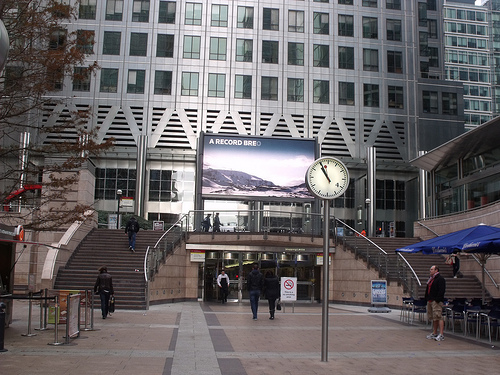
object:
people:
[93, 266, 116, 318]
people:
[246, 261, 266, 319]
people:
[216, 269, 230, 304]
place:
[0, 299, 500, 374]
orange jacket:
[360, 230, 367, 237]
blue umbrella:
[394, 225, 499, 256]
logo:
[372, 281, 386, 302]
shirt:
[424, 271, 447, 303]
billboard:
[192, 130, 322, 235]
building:
[0, 0, 500, 311]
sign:
[194, 131, 320, 203]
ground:
[0, 297, 497, 375]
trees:
[0, 0, 116, 348]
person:
[125, 216, 140, 252]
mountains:
[201, 162, 312, 199]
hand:
[319, 162, 332, 183]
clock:
[304, 156, 350, 202]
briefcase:
[108, 296, 116, 313]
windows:
[0, 0, 500, 234]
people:
[261, 269, 282, 320]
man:
[425, 264, 446, 342]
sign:
[279, 275, 299, 304]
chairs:
[399, 296, 500, 343]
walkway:
[153, 290, 500, 374]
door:
[198, 250, 320, 302]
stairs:
[333, 234, 496, 311]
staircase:
[54, 228, 187, 311]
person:
[359, 228, 367, 237]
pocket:
[432, 301, 442, 313]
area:
[0, 201, 500, 375]